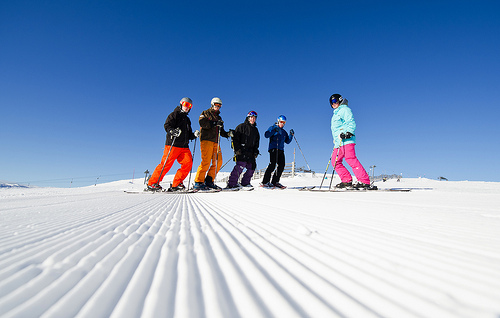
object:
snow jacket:
[330, 105, 358, 150]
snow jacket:
[264, 123, 296, 155]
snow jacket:
[230, 122, 261, 160]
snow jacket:
[198, 106, 230, 145]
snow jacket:
[158, 108, 196, 149]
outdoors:
[0, 158, 499, 317]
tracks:
[0, 192, 497, 317]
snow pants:
[329, 144, 372, 184]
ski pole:
[327, 141, 345, 188]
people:
[327, 92, 371, 189]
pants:
[194, 139, 225, 183]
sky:
[0, 0, 499, 189]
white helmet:
[209, 96, 224, 108]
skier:
[143, 97, 202, 191]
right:
[292, 1, 499, 187]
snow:
[0, 169, 499, 317]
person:
[262, 115, 294, 189]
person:
[227, 111, 260, 190]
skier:
[190, 97, 234, 191]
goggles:
[179, 102, 193, 110]